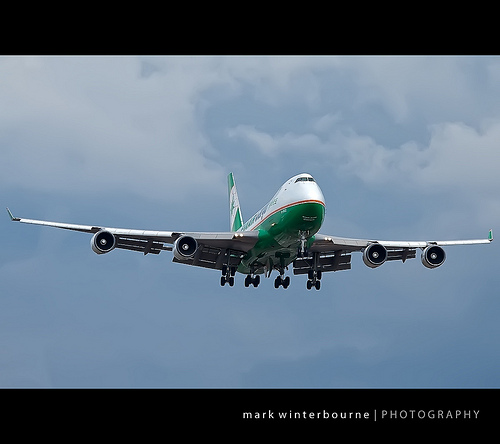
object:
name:
[241, 411, 372, 422]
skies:
[1, 55, 499, 389]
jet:
[6, 173, 495, 289]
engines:
[422, 247, 446, 268]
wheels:
[219, 275, 228, 287]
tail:
[226, 172, 242, 234]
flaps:
[116, 241, 410, 274]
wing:
[4, 206, 260, 262]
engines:
[90, 228, 122, 253]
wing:
[313, 228, 493, 258]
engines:
[362, 245, 392, 269]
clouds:
[1, 57, 210, 164]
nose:
[266, 182, 326, 232]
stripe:
[245, 199, 325, 230]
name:
[237, 203, 272, 231]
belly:
[250, 202, 326, 273]